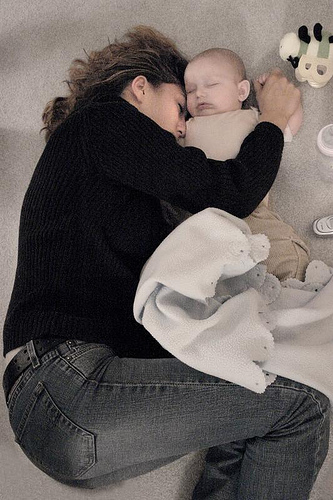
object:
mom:
[0, 23, 333, 500]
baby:
[161, 46, 310, 287]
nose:
[176, 111, 188, 140]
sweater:
[2, 89, 285, 357]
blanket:
[130, 205, 332, 408]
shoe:
[312, 214, 333, 239]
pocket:
[7, 378, 103, 489]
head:
[116, 25, 191, 146]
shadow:
[3, 124, 40, 220]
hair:
[39, 23, 189, 144]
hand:
[251, 66, 302, 119]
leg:
[28, 323, 332, 500]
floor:
[148, 471, 182, 499]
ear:
[237, 78, 252, 104]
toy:
[273, 20, 331, 89]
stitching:
[97, 376, 214, 390]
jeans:
[0, 327, 333, 500]